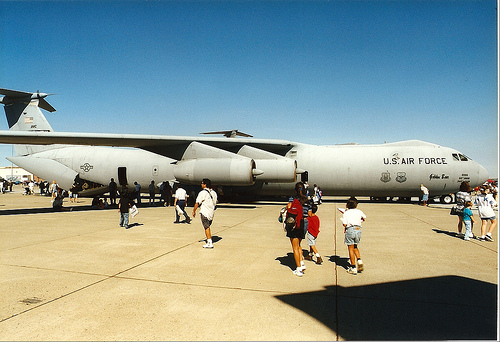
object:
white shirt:
[339, 208, 367, 227]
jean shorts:
[343, 224, 361, 246]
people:
[110, 170, 143, 230]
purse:
[282, 212, 296, 231]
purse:
[449, 203, 467, 215]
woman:
[283, 179, 311, 276]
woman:
[453, 181, 475, 241]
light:
[280, 24, 410, 81]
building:
[0, 165, 36, 182]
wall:
[0, 164, 35, 186]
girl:
[461, 200, 473, 242]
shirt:
[462, 207, 473, 221]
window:
[451, 153, 468, 161]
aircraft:
[0, 79, 493, 205]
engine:
[170, 140, 264, 182]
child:
[335, 197, 366, 276]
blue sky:
[0, 1, 498, 163]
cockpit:
[452, 152, 474, 162]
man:
[186, 166, 225, 248]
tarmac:
[0, 199, 496, 342]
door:
[117, 166, 128, 186]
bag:
[128, 200, 138, 216]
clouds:
[1, 0, 500, 120]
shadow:
[0, 201, 257, 222]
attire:
[195, 187, 220, 231]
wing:
[0, 127, 293, 151]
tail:
[2, 84, 91, 190]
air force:
[382, 155, 449, 166]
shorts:
[305, 231, 318, 245]